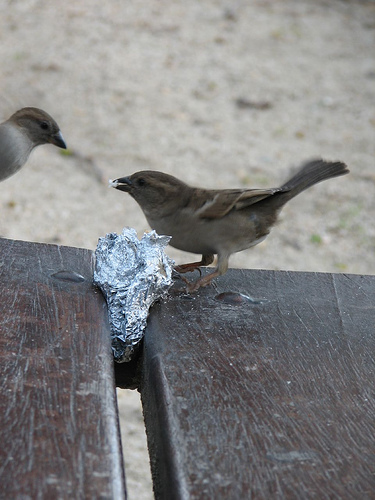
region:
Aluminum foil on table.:
[93, 230, 178, 355]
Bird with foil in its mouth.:
[110, 163, 334, 283]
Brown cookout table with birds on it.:
[185, 267, 371, 496]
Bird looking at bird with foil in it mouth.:
[4, 99, 72, 228]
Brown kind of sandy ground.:
[35, 12, 361, 102]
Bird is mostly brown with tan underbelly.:
[138, 169, 351, 264]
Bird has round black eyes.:
[7, 100, 70, 176]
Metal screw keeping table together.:
[212, 285, 264, 325]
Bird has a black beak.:
[106, 160, 128, 194]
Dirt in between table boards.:
[131, 364, 184, 499]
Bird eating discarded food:
[104, 148, 358, 303]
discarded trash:
[90, 221, 180, 365]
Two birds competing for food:
[1, 71, 354, 317]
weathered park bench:
[0, 237, 371, 495]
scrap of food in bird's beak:
[104, 173, 117, 193]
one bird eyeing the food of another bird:
[1, 94, 352, 295]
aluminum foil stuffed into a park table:
[92, 222, 178, 367]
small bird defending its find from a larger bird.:
[0, 97, 352, 365]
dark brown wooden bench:
[0, 239, 373, 498]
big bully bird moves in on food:
[1, 87, 352, 303]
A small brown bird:
[112, 151, 352, 292]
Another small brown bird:
[0, 106, 66, 190]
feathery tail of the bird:
[278, 149, 348, 201]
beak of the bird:
[111, 173, 135, 196]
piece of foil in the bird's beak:
[107, 179, 119, 185]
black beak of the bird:
[50, 134, 66, 151]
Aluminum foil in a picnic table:
[82, 224, 176, 362]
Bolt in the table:
[214, 287, 253, 306]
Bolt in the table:
[48, 260, 86, 284]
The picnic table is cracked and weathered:
[0, 237, 373, 498]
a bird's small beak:
[109, 175, 133, 193]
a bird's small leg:
[182, 252, 228, 297]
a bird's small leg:
[173, 251, 214, 272]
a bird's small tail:
[275, 155, 347, 196]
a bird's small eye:
[131, 176, 147, 186]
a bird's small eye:
[38, 120, 52, 133]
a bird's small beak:
[50, 129, 70, 152]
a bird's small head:
[110, 167, 172, 215]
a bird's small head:
[9, 103, 69, 150]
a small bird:
[101, 134, 352, 312]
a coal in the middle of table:
[112, 219, 154, 332]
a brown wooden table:
[211, 342, 268, 436]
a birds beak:
[90, 174, 137, 197]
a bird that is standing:
[190, 174, 235, 262]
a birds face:
[22, 100, 34, 154]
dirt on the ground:
[153, 44, 248, 138]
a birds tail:
[250, 158, 335, 244]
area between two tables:
[121, 429, 190, 497]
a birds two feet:
[184, 250, 218, 291]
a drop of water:
[66, 248, 81, 304]